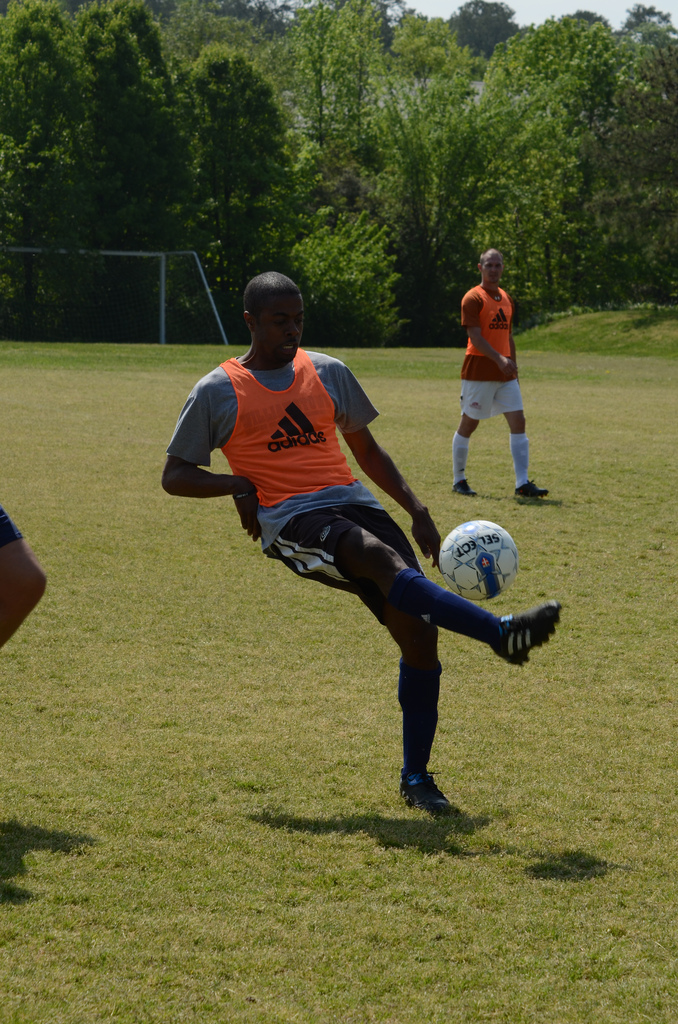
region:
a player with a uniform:
[443, 238, 558, 506]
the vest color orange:
[211, 347, 368, 514]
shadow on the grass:
[231, 793, 636, 894]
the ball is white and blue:
[431, 510, 531, 608]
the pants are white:
[453, 376, 528, 427]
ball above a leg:
[402, 498, 581, 685]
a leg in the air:
[290, 499, 579, 676]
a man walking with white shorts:
[448, 248, 580, 519]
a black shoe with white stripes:
[482, 601, 571, 660]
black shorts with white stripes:
[264, 502, 434, 608]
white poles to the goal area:
[7, 228, 238, 360]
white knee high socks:
[448, 427, 540, 492]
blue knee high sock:
[385, 565, 508, 656]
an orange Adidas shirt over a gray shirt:
[197, 341, 370, 494]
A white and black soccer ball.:
[437, 519, 517, 605]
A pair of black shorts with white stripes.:
[259, 504, 442, 622]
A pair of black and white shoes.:
[488, 598, 562, 665]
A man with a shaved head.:
[240, 269, 303, 366]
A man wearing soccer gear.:
[447, 245, 545, 501]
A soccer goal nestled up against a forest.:
[0, 243, 228, 344]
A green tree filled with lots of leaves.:
[246, 198, 407, 345]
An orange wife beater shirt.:
[459, 283, 511, 359]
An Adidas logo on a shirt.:
[482, 300, 510, 330]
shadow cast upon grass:
[237, 789, 633, 887]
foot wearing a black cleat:
[501, 581, 593, 682]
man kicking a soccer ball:
[154, 261, 569, 845]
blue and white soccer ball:
[426, 514, 525, 596]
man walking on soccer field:
[447, 225, 553, 512]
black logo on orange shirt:
[487, 304, 510, 333]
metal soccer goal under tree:
[13, 237, 232, 355]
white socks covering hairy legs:
[446, 432, 554, 488]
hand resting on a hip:
[215, 468, 263, 539]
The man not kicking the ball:
[443, 247, 555, 502]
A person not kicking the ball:
[440, 241, 552, 502]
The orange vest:
[455, 280, 523, 357]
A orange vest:
[203, 364, 358, 496]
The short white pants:
[448, 379, 536, 431]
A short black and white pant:
[264, 504, 412, 577]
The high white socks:
[439, 427, 534, 483]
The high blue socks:
[376, 570, 491, 747]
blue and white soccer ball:
[416, 512, 508, 616]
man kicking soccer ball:
[155, 229, 552, 841]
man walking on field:
[427, 221, 565, 507]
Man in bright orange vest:
[446, 250, 551, 501]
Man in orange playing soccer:
[162, 271, 567, 814]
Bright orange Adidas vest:
[216, 348, 360, 510]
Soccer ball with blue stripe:
[439, 519, 522, 600]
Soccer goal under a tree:
[2, 243, 232, 349]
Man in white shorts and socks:
[447, 246, 549, 501]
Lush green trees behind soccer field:
[8, 9, 674, 342]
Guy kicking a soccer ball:
[163, 271, 563, 808]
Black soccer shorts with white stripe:
[266, 506, 424, 621]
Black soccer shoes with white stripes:
[403, 598, 562, 820]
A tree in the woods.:
[294, 206, 408, 342]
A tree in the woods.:
[192, 46, 298, 283]